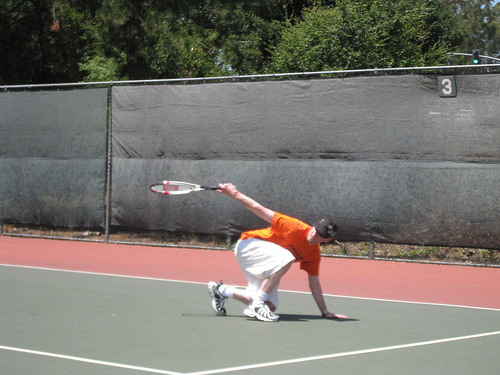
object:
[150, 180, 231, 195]
tennis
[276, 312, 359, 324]
shadow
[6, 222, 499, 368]
surface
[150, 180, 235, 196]
racket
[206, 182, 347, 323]
male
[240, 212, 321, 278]
orange shirt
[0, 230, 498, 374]
court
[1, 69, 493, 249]
fencing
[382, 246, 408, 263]
grass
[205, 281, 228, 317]
men's shoes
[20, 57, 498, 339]
tennis court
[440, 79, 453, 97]
number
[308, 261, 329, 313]
arm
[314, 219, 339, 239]
hat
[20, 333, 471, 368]
lines